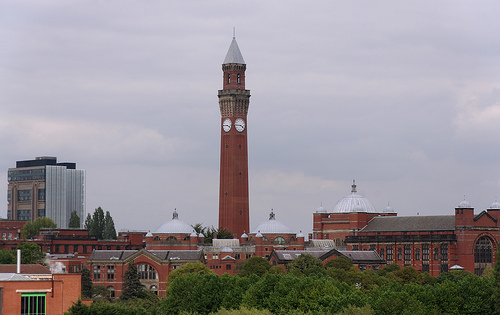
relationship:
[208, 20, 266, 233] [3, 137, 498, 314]
tower in town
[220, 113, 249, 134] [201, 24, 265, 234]
clocks in tower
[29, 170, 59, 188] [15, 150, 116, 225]
window on building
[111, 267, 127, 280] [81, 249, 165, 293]
window on building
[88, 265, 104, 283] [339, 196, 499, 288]
window on building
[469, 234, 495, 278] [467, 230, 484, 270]
window on building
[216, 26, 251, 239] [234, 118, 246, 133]
tower has clock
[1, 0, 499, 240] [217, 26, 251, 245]
grey sky behind clock tower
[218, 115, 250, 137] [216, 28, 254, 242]
clock area on clock tower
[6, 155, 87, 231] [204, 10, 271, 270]
building left of tower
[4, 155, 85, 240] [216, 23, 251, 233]
building left of tower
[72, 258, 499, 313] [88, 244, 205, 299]
trees in front of building